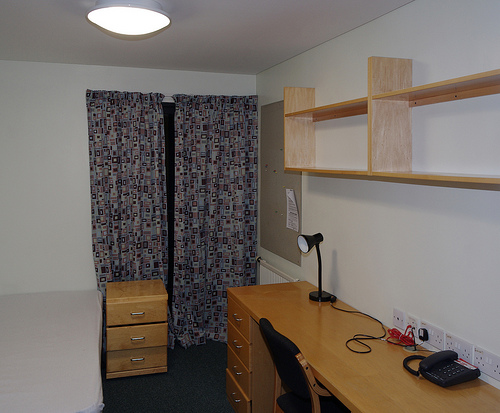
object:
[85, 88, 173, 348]
panel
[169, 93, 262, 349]
panel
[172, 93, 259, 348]
curtain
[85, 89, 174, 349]
curtain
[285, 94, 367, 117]
shelf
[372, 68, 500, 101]
shelf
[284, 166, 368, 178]
shelf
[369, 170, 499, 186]
shelf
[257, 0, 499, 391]
wall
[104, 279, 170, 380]
dresser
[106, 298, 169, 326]
drawer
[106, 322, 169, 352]
drawer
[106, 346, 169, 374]
drawer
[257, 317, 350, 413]
chair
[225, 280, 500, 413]
desk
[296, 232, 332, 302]
lamp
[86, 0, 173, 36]
light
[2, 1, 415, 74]
ceiling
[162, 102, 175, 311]
window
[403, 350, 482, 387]
telephone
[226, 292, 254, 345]
drawer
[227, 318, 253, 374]
drawer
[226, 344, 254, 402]
drawer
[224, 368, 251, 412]
drawer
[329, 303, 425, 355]
cord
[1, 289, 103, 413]
twin bed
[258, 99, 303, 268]
bulletin board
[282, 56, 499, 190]
shelf set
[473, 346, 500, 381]
electrical outlet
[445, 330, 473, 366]
electrical outlet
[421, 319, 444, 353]
electrical outlet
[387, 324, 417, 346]
cord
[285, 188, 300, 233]
paper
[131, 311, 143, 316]
drawer pull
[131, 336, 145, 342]
drawer pull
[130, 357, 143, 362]
drawer pull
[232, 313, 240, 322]
handle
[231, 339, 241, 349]
handle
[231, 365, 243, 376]
handle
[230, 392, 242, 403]
handle